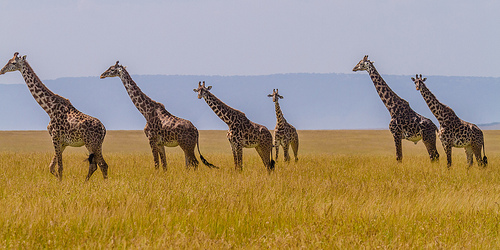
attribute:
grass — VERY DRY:
[14, 130, 479, 235]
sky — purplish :
[2, 3, 498, 74]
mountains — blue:
[8, 69, 497, 126]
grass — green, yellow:
[7, 125, 499, 247]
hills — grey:
[0, 74, 494, 128]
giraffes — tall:
[0, 49, 489, 181]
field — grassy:
[0, 125, 497, 248]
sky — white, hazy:
[0, 3, 497, 82]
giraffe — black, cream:
[191, 80, 279, 173]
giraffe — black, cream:
[98, 58, 218, 171]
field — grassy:
[1, 115, 496, 244]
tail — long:
[479, 131, 487, 176]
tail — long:
[266, 137, 280, 173]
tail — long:
[191, 130, 220, 172]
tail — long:
[85, 129, 111, 163]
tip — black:
[480, 155, 487, 165]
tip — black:
[267, 158, 276, 170]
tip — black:
[197, 154, 217, 171]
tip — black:
[82, 153, 102, 169]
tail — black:
[84, 152, 95, 164]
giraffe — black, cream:
[410, 73, 490, 171]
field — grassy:
[2, 152, 498, 247]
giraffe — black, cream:
[353, 54, 441, 163]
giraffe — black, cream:
[269, 87, 301, 165]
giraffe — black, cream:
[0, 51, 104, 180]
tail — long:
[85, 126, 103, 167]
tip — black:
[84, 151, 95, 163]